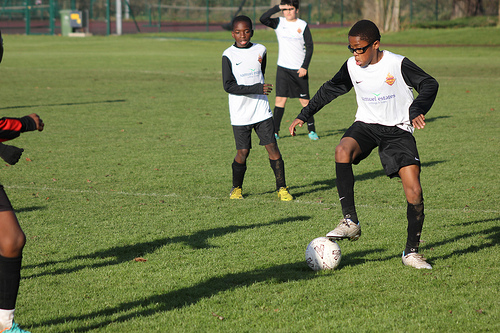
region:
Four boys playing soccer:
[3, 7, 438, 275]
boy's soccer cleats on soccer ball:
[300, 217, 367, 270]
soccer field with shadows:
[56, 47, 212, 306]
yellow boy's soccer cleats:
[228, 184, 304, 219]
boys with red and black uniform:
[1, 100, 35, 328]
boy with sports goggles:
[348, 37, 383, 64]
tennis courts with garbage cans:
[8, 5, 223, 37]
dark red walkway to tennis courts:
[390, 35, 495, 52]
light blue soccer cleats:
[269, 130, 322, 145]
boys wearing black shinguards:
[6, 98, 459, 330]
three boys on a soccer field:
[186, 0, 453, 298]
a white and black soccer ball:
[280, 222, 359, 286]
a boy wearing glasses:
[334, 14, 395, 86]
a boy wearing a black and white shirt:
[293, 7, 423, 214]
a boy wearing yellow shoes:
[224, 15, 289, 205]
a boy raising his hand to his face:
[263, 0, 310, 27]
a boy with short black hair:
[338, 17, 390, 72]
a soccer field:
[76, 36, 206, 282]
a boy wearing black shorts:
[316, 15, 430, 226]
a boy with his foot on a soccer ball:
[294, 17, 396, 300]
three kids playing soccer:
[187, 4, 471, 296]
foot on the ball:
[293, 210, 368, 275]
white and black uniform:
[204, 40, 297, 185]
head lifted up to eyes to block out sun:
[255, 3, 305, 31]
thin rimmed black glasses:
[340, 37, 378, 57]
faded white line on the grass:
[27, 176, 171, 211]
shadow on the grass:
[32, 255, 301, 331]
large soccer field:
[7, 33, 496, 330]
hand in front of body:
[221, 57, 278, 104]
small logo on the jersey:
[382, 71, 399, 90]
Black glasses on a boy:
[344, 42, 373, 54]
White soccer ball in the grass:
[301, 238, 345, 273]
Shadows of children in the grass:
[76, 217, 310, 318]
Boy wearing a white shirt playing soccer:
[220, 46, 279, 123]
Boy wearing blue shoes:
[269, 128, 324, 141]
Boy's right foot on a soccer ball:
[311, 215, 368, 265]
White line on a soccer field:
[48, 174, 495, 224]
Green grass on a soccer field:
[73, 115, 202, 178]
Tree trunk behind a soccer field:
[448, 2, 482, 25]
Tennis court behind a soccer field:
[114, 0, 291, 28]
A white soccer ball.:
[304, 229, 342, 271]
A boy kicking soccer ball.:
[305, 16, 448, 273]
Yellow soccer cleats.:
[221, 170, 296, 202]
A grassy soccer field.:
[5, 42, 495, 327]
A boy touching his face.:
[261, 2, 310, 31]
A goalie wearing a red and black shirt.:
[0, 31, 57, 331]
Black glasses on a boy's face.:
[342, 42, 382, 54]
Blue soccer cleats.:
[268, 122, 320, 142]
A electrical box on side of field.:
[68, 10, 86, 27]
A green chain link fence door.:
[25, 2, 54, 33]